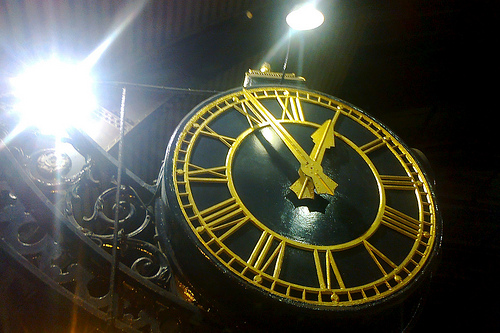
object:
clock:
[156, 69, 446, 326]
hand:
[291, 110, 342, 207]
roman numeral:
[275, 93, 305, 123]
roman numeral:
[196, 124, 236, 148]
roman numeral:
[376, 199, 426, 242]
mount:
[1, 90, 196, 332]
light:
[287, 2, 324, 34]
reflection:
[284, 198, 323, 240]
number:
[357, 134, 387, 156]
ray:
[81, 4, 153, 60]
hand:
[241, 89, 339, 196]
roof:
[1, 2, 271, 81]